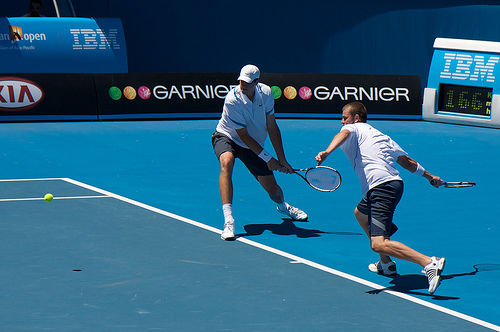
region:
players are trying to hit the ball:
[171, 39, 441, 305]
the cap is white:
[225, 50, 277, 107]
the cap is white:
[228, 62, 262, 90]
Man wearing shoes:
[362, 250, 447, 295]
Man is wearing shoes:
[365, 247, 451, 297]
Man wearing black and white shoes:
[365, 250, 447, 296]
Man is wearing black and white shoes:
[364, 252, 447, 300]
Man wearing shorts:
[353, 181, 409, 239]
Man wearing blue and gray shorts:
[356, 179, 407, 240]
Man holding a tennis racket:
[425, 168, 478, 195]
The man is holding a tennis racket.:
[197, 53, 344, 245]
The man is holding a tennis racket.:
[307, 91, 481, 303]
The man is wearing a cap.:
[208, 48, 345, 241]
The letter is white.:
[312, 79, 331, 104]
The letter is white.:
[328, 80, 345, 106]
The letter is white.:
[342, 79, 359, 109]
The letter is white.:
[356, 80, 376, 107]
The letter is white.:
[376, 79, 396, 106]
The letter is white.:
[393, 83, 411, 104]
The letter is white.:
[151, 78, 170, 107]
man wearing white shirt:
[364, 144, 378, 161]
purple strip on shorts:
[368, 217, 387, 231]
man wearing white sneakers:
[418, 257, 445, 294]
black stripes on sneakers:
[427, 266, 436, 281]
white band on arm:
[412, 159, 427, 181]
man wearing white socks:
[223, 204, 231, 216]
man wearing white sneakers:
[215, 220, 242, 250]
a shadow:
[251, 215, 311, 241]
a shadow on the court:
[385, 271, 422, 297]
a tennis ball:
[40, 186, 60, 207]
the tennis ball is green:
[38, 185, 58, 207]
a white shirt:
[361, 134, 394, 173]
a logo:
[3, 80, 41, 112]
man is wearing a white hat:
[241, 67, 260, 86]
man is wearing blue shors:
[372, 194, 389, 227]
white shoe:
[419, 259, 446, 295]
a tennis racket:
[303, 161, 349, 191]